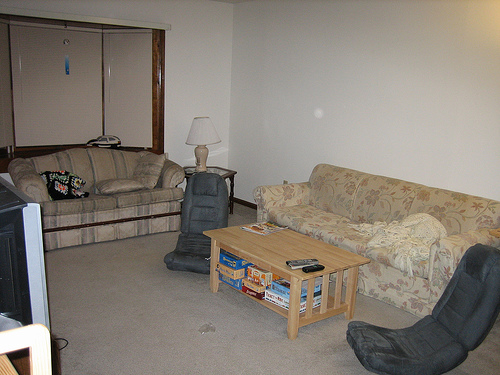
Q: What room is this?
A: Den.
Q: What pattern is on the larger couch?
A: Floral.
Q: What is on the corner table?
A: A lamp.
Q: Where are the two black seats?
A: On the floor.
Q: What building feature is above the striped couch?
A: A window.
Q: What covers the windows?
A: Blinds.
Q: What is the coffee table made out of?
A: Wood.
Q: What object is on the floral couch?
A: A blanket.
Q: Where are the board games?
A: Under the coffee table.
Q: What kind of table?
A: Coffee.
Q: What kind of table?
A: Wood.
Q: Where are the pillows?
A: Couch.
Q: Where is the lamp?
A: On the table.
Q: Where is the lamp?
A: In the corner.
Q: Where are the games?
A: Under the table.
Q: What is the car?
A: Toy.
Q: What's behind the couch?
A: Wall.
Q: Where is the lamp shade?
A: On the lamp.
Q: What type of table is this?
A: Wood.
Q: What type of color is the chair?
A: Black.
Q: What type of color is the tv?
A: Black and silver.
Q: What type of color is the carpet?
A: Grey.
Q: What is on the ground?
A: Carpet.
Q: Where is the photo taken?
A: Living room.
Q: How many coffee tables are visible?
A: One.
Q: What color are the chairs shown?
A: Black.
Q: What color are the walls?
A: White.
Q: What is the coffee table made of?
A: Wood.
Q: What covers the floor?
A: Carpet.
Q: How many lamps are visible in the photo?
A: One.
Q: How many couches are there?
A: Two.